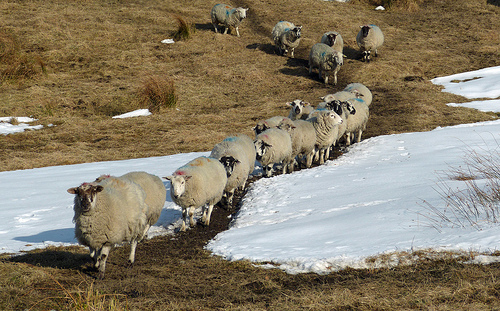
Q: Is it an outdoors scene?
A: Yes, it is outdoors.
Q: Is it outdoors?
A: Yes, it is outdoors.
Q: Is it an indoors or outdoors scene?
A: It is outdoors.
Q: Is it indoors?
A: No, it is outdoors.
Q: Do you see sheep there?
A: Yes, there is a sheep.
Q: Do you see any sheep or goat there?
A: Yes, there is a sheep.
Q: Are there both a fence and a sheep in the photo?
A: No, there is a sheep but no fences.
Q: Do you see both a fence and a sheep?
A: No, there is a sheep but no fences.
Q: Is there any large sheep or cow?
A: Yes, there is a large sheep.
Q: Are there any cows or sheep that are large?
A: Yes, the sheep is large.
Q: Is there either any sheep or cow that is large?
A: Yes, the sheep is large.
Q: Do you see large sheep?
A: Yes, there is a large sheep.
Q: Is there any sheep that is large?
A: Yes, there is a sheep that is large.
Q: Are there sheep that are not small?
A: Yes, there is a large sheep.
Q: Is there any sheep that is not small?
A: Yes, there is a large sheep.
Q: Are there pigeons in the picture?
A: No, there are no pigeons.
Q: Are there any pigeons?
A: No, there are no pigeons.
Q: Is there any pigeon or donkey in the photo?
A: No, there are no pigeons or donkeys.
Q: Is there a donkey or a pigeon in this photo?
A: No, there are no pigeons or donkeys.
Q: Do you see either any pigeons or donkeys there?
A: No, there are no pigeons or donkeys.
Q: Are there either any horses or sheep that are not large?
A: No, there is a sheep but it is large.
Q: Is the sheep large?
A: Yes, the sheep is large.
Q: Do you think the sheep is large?
A: Yes, the sheep is large.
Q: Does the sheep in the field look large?
A: Yes, the sheep is large.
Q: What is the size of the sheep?
A: The sheep is large.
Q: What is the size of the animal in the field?
A: The sheep is large.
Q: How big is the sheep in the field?
A: The sheep is large.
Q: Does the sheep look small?
A: No, the sheep is large.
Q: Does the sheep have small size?
A: No, the sheep is large.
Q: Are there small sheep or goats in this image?
A: No, there is a sheep but it is large.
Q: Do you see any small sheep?
A: No, there is a sheep but it is large.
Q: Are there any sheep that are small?
A: No, there is a sheep but it is large.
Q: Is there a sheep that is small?
A: No, there is a sheep but it is large.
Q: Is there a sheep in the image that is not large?
A: No, there is a sheep but it is large.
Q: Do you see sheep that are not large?
A: No, there is a sheep but it is large.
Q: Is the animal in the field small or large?
A: The sheep is large.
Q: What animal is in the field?
A: The animal is a sheep.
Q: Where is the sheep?
A: The sheep is in the field.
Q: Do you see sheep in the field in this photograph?
A: Yes, there is a sheep in the field.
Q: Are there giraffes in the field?
A: No, there is a sheep in the field.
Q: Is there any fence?
A: No, there are no fences.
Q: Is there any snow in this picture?
A: Yes, there is snow.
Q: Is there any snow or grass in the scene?
A: Yes, there is snow.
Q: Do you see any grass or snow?
A: Yes, there is snow.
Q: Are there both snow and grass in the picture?
A: Yes, there are both snow and grass.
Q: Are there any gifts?
A: No, there are no gifts.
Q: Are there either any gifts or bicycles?
A: No, there are no gifts or bicycles.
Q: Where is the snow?
A: The snow is in the field.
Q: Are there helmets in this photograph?
A: No, there are no helmets.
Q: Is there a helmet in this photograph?
A: No, there are no helmets.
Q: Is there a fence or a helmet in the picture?
A: No, there are no helmets or fences.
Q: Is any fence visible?
A: No, there are no fences.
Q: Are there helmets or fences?
A: No, there are no fences or helmets.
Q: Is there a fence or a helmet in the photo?
A: No, there are no fences or helmets.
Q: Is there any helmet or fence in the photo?
A: No, there are no fences or helmets.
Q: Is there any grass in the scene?
A: Yes, there is grass.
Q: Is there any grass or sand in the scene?
A: Yes, there is grass.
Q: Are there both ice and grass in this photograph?
A: No, there is grass but no ice.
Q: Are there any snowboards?
A: No, there are no snowboards.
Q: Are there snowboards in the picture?
A: No, there are no snowboards.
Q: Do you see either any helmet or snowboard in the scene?
A: No, there are no snowboards or helmets.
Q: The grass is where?
A: The grass is in the field.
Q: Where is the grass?
A: The grass is in the field.